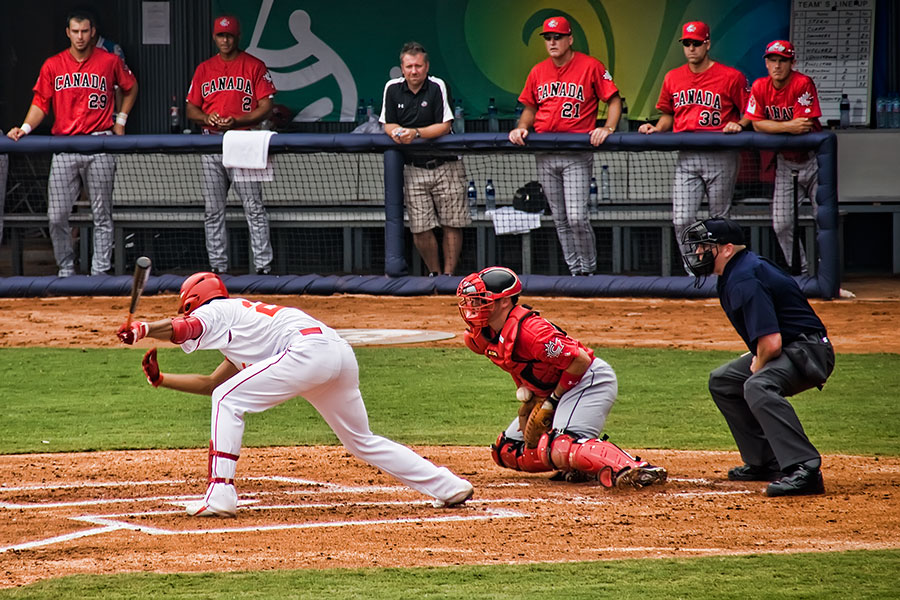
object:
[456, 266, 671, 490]
catcher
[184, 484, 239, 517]
home plate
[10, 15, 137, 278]
man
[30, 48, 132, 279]
uniform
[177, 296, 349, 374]
shirt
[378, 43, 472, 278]
man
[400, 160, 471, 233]
shorts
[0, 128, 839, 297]
dug out